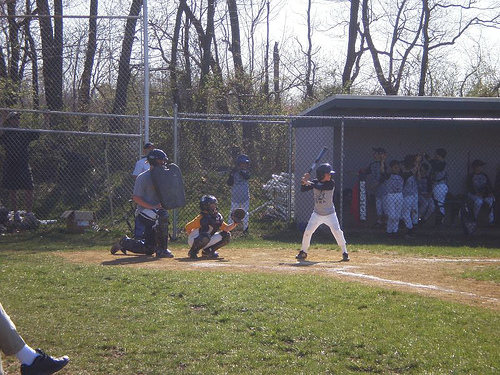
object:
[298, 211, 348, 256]
pants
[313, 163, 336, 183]
head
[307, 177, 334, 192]
arm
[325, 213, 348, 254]
leg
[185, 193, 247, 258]
catcher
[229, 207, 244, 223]
mitt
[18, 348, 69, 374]
shoe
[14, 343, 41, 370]
sock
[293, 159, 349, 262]
boy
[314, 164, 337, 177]
bat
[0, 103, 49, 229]
man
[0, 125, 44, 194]
clothes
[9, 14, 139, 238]
fence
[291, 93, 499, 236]
building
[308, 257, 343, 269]
home plate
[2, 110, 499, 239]
fence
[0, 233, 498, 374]
field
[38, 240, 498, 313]
dirt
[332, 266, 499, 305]
line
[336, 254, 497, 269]
line